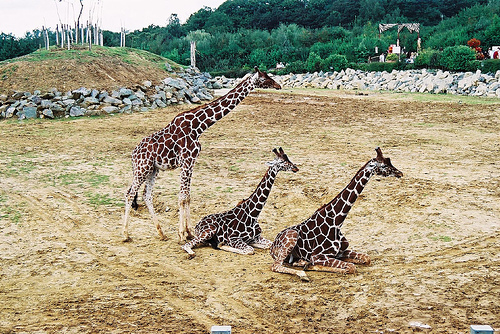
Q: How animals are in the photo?
A: Three.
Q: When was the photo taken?
A: During the day.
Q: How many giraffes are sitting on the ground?
A: Two.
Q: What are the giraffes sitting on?
A: Dirt.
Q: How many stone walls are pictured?
A: Two.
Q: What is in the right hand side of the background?
A: Trees.